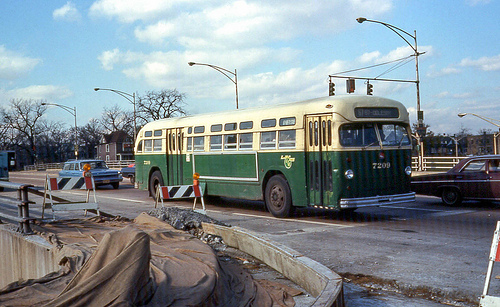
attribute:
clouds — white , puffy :
[88, 2, 362, 90]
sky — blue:
[1, 2, 499, 142]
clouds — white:
[1, 86, 68, 105]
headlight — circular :
[340, 164, 360, 186]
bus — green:
[112, 91, 417, 213]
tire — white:
[252, 172, 294, 227]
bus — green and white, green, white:
[131, 92, 416, 217]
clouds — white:
[115, 8, 290, 51]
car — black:
[414, 145, 499, 208]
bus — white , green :
[125, 96, 417, 207]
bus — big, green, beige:
[129, 83, 422, 223]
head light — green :
[342, 168, 353, 179]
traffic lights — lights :
[327, 74, 372, 99]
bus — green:
[145, 100, 450, 235]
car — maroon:
[415, 139, 498, 206]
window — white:
[221, 122, 241, 152]